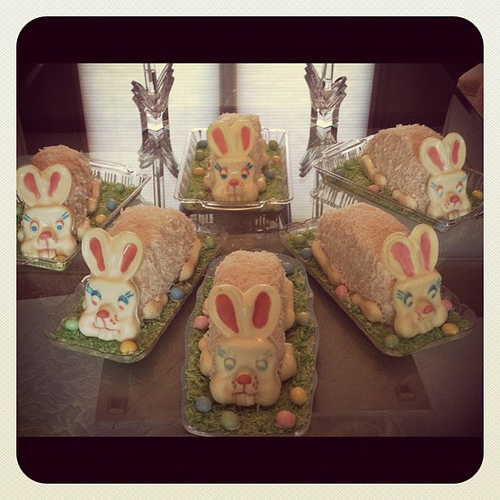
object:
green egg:
[62, 316, 79, 331]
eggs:
[275, 407, 296, 431]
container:
[173, 114, 296, 215]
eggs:
[192, 165, 207, 177]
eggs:
[95, 211, 109, 228]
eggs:
[437, 320, 459, 335]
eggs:
[217, 407, 242, 434]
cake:
[66, 201, 197, 348]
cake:
[198, 109, 270, 201]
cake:
[357, 119, 476, 234]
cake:
[191, 246, 298, 411]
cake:
[308, 203, 461, 334]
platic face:
[18, 208, 73, 266]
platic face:
[76, 229, 141, 341]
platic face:
[205, 333, 283, 402]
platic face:
[381, 271, 448, 334]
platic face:
[422, 167, 474, 215]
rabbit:
[201, 108, 268, 199]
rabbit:
[358, 122, 473, 219]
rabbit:
[312, 198, 450, 341]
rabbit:
[198, 246, 297, 406]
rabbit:
[76, 201, 204, 340]